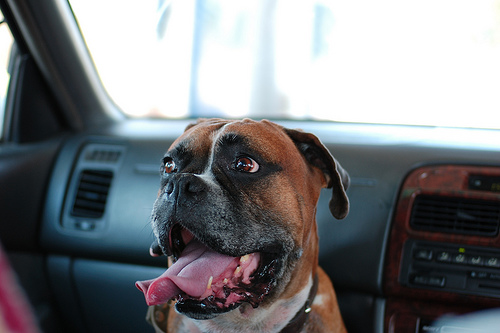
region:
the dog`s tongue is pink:
[108, 236, 264, 313]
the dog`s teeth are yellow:
[200, 239, 250, 304]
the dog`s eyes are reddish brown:
[137, 140, 271, 178]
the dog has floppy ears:
[277, 107, 365, 254]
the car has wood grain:
[369, 149, 494, 272]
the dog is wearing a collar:
[271, 252, 329, 331]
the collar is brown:
[266, 240, 359, 327]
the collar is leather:
[266, 240, 345, 330]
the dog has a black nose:
[135, 168, 250, 233]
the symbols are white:
[395, 236, 497, 279]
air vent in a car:
[50, 153, 120, 250]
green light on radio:
[440, 240, 474, 262]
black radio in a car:
[385, 243, 494, 308]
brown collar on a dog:
[277, 256, 352, 329]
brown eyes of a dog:
[144, 142, 282, 192]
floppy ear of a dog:
[311, 141, 371, 233]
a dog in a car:
[89, 111, 381, 314]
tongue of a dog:
[174, 220, 283, 325]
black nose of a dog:
[145, 163, 212, 222]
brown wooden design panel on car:
[362, 160, 492, 314]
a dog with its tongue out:
[102, 67, 458, 328]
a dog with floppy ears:
[85, 60, 368, 326]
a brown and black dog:
[65, 54, 397, 328]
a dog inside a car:
[44, 30, 382, 330]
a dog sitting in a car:
[62, 52, 397, 330]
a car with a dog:
[74, 37, 415, 330]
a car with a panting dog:
[91, 71, 428, 327]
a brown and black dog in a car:
[0, 10, 446, 328]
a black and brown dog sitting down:
[72, 78, 393, 330]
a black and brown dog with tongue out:
[4, 27, 442, 327]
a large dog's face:
[137, 110, 345, 330]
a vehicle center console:
[372, 161, 497, 324]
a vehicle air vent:
[56, 156, 113, 231]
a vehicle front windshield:
[60, 0, 499, 125]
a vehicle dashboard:
[39, 120, 491, 325]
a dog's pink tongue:
[128, 246, 230, 307]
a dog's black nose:
[154, 174, 203, 201]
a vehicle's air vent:
[400, 191, 492, 238]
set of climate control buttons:
[406, 239, 498, 270]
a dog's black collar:
[128, 259, 327, 330]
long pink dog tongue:
[138, 232, 258, 318]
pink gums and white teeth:
[222, 246, 256, 293]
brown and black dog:
[148, 110, 310, 331]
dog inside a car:
[149, 95, 284, 330]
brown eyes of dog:
[217, 148, 264, 175]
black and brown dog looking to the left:
[162, 122, 329, 328]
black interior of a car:
[64, 146, 130, 239]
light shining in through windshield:
[130, 8, 489, 119]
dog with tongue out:
[127, 133, 290, 328]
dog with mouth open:
[157, 130, 322, 327]